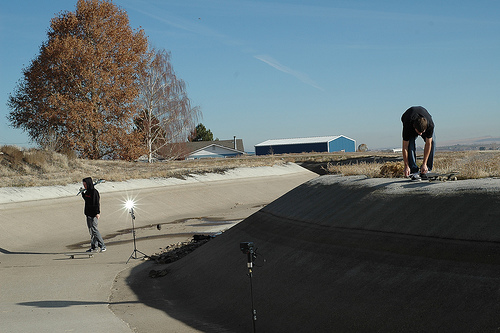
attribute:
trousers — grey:
[85, 215, 105, 249]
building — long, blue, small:
[253, 135, 356, 156]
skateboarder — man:
[76, 177, 106, 254]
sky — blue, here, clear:
[1, 1, 499, 152]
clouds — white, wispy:
[253, 46, 316, 92]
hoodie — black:
[80, 176, 100, 217]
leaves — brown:
[54, 44, 91, 99]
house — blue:
[476, 146, 485, 153]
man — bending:
[399, 106, 435, 179]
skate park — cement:
[0, 162, 499, 332]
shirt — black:
[400, 105, 434, 141]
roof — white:
[254, 135, 345, 148]